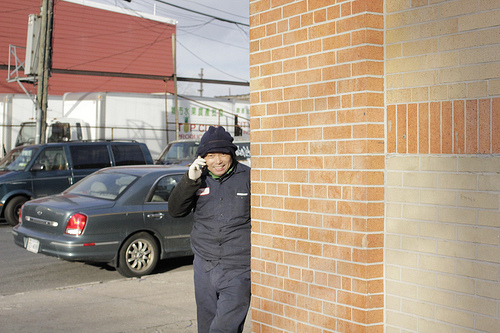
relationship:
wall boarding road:
[53, 88, 195, 138] [9, 239, 76, 290]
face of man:
[208, 154, 233, 175] [149, 109, 310, 331]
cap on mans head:
[182, 103, 272, 160] [190, 107, 270, 177]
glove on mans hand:
[190, 159, 206, 184] [189, 156, 208, 180]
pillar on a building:
[248, 0, 385, 332] [248, 0, 498, 330]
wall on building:
[386, 2, 498, 331] [248, 0, 498, 330]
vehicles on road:
[5, 140, 252, 270] [2, 214, 132, 308]